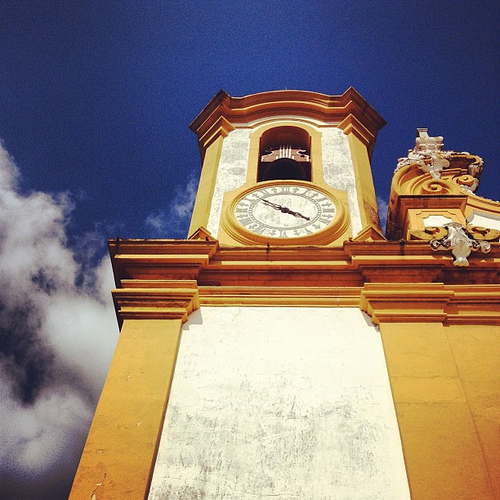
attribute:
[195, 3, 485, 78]
sky — blue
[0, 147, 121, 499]
cloud — white, fluffy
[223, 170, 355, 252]
clock — round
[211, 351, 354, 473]
space — beige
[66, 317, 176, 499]
wall — brown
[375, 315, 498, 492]
wall — brown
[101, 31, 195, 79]
skies — blue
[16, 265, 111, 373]
cloud — white, soft, fluffy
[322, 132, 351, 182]
design — beautiful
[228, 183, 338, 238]
clock interior — white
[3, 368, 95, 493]
cloud — white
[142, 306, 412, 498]
wall — white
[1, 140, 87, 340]
cloud — white